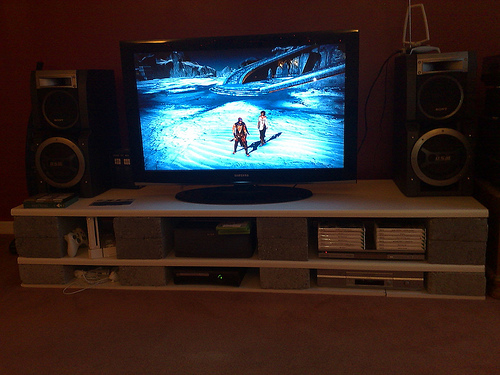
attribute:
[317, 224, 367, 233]
dvd — bunched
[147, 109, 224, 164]
snow — blue 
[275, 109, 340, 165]
snow — blue 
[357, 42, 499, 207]
speakers — white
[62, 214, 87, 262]
controller — white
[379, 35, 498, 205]
speakers — black , grey 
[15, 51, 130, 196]
speaker — black 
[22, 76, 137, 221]
frame — grey 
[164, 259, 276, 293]
xbox — black 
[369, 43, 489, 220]
speaker — black 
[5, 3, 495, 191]
wall — brown 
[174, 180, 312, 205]
tv stand — black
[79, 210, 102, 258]
wii — white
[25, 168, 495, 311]
desk — grey 